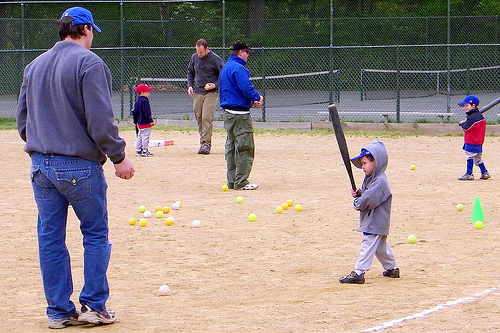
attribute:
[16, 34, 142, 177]
shirt — dark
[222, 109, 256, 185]
pants — grey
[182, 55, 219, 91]
sweater — gray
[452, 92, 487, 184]
boy — young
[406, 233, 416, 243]
baseball — light green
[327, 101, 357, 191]
baseball bat — black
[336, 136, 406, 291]
boy — little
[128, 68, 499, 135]
nets — group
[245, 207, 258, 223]
ball — white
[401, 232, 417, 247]
ball — white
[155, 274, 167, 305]
ball — white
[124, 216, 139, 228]
ball — white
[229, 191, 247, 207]
ball — white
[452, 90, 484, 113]
hat — blue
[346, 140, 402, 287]
boy — young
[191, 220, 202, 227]
ball — white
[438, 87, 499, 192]
boy — little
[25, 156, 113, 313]
jeans — blue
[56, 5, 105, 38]
baseball cap — blue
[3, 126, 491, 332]
field — playing, baseball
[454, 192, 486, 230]
cone — green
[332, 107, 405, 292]
child — small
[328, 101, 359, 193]
baseball bat — small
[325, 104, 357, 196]
bat — black, baseball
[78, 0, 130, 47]
hat — blue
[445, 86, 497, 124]
cap — baseball, red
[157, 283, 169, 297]
baseball — white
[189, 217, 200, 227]
baseball — white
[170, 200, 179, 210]
baseball — white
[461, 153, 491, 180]
socks — long, blue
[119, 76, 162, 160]
boy — little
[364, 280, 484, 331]
line — white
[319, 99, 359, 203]
bat — metal